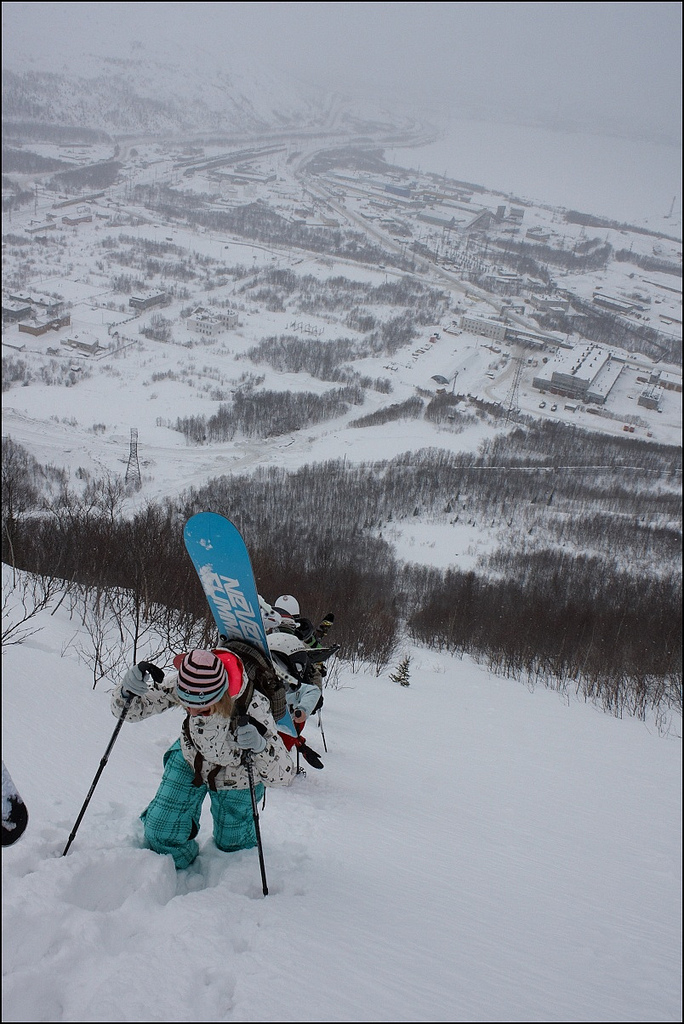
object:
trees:
[74, 517, 110, 676]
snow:
[325, 702, 625, 1013]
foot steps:
[55, 852, 144, 924]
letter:
[208, 586, 230, 603]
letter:
[205, 570, 224, 588]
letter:
[220, 573, 245, 597]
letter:
[216, 602, 237, 620]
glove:
[232, 718, 269, 756]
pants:
[138, 737, 265, 871]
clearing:
[395, 521, 479, 572]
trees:
[662, 570, 677, 669]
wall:
[552, 380, 569, 394]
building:
[631, 366, 683, 416]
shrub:
[602, 577, 626, 723]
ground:
[528, 674, 683, 812]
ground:
[418, 673, 683, 876]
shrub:
[604, 586, 633, 720]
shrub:
[540, 603, 555, 667]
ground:
[307, 659, 682, 1023]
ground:
[406, 685, 682, 1012]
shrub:
[472, 607, 495, 678]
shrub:
[380, 594, 400, 658]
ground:
[333, 673, 683, 1019]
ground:
[315, 689, 682, 1022]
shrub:
[381, 640, 426, 687]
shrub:
[69, 539, 113, 632]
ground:
[333, 695, 684, 1021]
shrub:
[120, 555, 161, 666]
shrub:
[84, 531, 106, 611]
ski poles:
[59, 658, 163, 869]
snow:
[0, 838, 406, 1022]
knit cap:
[164, 644, 234, 717]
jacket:
[111, 662, 294, 790]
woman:
[107, 638, 299, 876]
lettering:
[226, 590, 250, 613]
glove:
[118, 651, 157, 705]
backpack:
[214, 629, 290, 729]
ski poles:
[236, 722, 275, 901]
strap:
[136, 655, 167, 695]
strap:
[226, 707, 255, 736]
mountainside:
[31, 158, 661, 620]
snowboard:
[177, 507, 303, 743]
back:
[217, 633, 284, 729]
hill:
[317, 701, 682, 1016]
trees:
[366, 583, 392, 662]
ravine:
[98, 477, 681, 684]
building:
[530, 343, 625, 407]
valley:
[331, 433, 681, 660]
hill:
[177, 666, 678, 1022]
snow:
[284, 871, 683, 1023]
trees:
[614, 555, 632, 672]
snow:
[451, 147, 546, 179]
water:
[392, 106, 683, 204]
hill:
[51, 611, 682, 1022]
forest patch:
[186, 378, 339, 451]